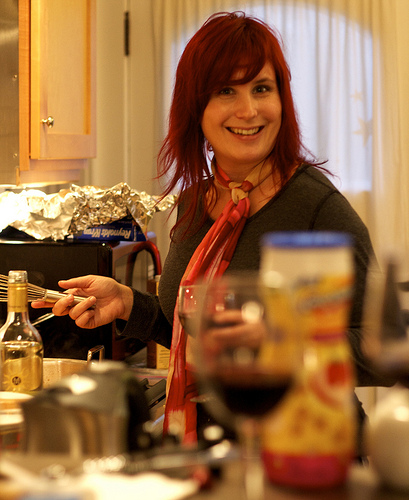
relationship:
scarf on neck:
[200, 154, 287, 202] [203, 147, 319, 223]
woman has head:
[142, 21, 389, 426] [149, 15, 314, 189]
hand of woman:
[43, 272, 131, 335] [142, 21, 389, 426]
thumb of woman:
[56, 272, 108, 291] [142, 21, 389, 426]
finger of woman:
[43, 293, 99, 333] [142, 21, 389, 426]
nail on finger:
[60, 268, 74, 293] [43, 293, 99, 333]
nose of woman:
[228, 93, 268, 125] [142, 21, 389, 426]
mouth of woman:
[217, 121, 293, 150] [142, 21, 389, 426]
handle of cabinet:
[39, 110, 69, 147] [25, 9, 101, 183]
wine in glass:
[178, 286, 318, 417] [174, 271, 306, 498]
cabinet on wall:
[25, 9, 101, 183] [39, 28, 168, 196]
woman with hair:
[142, 21, 389, 426] [123, 20, 349, 170]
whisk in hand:
[10, 260, 116, 327] [43, 272, 131, 335]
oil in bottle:
[0, 210, 61, 417] [8, 262, 51, 401]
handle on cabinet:
[39, 110, 69, 147] [24, 0, 99, 162]